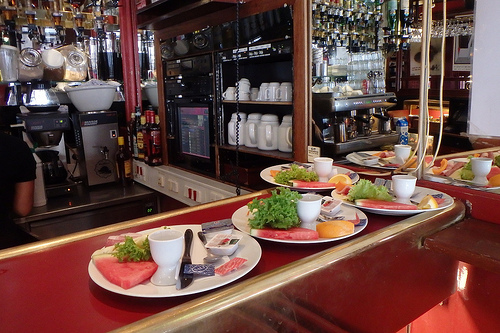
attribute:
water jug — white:
[273, 110, 293, 156]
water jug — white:
[254, 110, 281, 153]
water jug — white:
[243, 112, 258, 147]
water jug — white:
[224, 106, 248, 152]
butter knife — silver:
[178, 227, 194, 292]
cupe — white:
[145, 229, 186, 278]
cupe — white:
[292, 191, 323, 223]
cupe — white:
[390, 174, 420, 201]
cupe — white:
[305, 156, 337, 187]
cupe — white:
[388, 141, 415, 165]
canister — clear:
[18, 25, 50, 87]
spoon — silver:
[179, 232, 232, 278]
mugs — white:
[222, 76, 297, 106]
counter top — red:
[3, 188, 292, 331]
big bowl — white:
[68, 82, 119, 109]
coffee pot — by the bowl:
[26, 112, 79, 202]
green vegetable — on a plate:
[245, 187, 299, 227]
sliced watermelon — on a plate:
[91, 251, 156, 291]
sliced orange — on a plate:
[316, 220, 356, 234]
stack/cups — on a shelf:
[236, 72, 253, 102]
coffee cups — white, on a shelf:
[256, 80, 292, 102]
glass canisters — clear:
[2, 44, 89, 80]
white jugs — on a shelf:
[242, 112, 295, 150]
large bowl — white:
[64, 83, 120, 108]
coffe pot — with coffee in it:
[17, 77, 61, 113]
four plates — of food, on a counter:
[72, 154, 454, 299]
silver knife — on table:
[173, 223, 193, 287]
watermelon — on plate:
[92, 251, 159, 288]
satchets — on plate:
[176, 254, 252, 282]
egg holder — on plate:
[148, 230, 187, 288]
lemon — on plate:
[325, 172, 349, 184]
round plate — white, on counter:
[85, 220, 264, 298]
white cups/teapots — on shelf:
[222, 76, 292, 152]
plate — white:
[63, 214, 271, 303]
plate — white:
[226, 187, 376, 250]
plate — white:
[324, 170, 464, 226]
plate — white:
[251, 154, 361, 193]